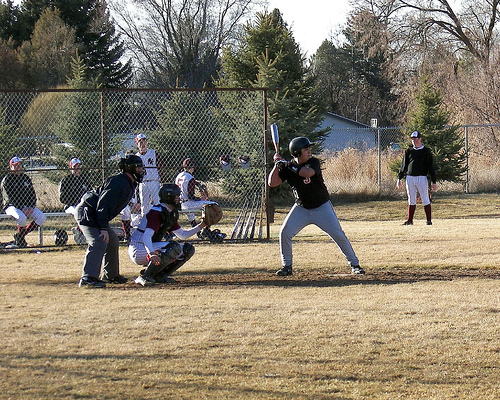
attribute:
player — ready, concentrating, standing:
[266, 134, 366, 277]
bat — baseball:
[270, 123, 283, 173]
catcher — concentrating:
[127, 182, 204, 287]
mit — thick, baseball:
[202, 202, 224, 225]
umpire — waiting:
[72, 154, 146, 289]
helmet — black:
[288, 136, 315, 156]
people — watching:
[1, 134, 219, 248]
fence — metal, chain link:
[0, 86, 270, 252]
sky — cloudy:
[1, 1, 498, 88]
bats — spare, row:
[229, 186, 265, 241]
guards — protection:
[140, 240, 198, 282]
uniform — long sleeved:
[397, 145, 437, 225]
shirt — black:
[274, 155, 330, 210]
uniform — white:
[127, 204, 201, 266]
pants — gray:
[279, 199, 361, 266]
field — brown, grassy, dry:
[3, 195, 499, 399]